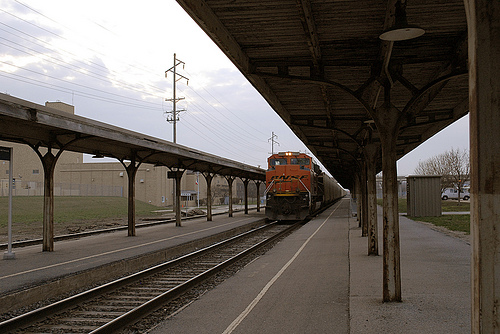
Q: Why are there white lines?
A: For boundaries.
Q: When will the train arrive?
A: Now.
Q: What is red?
A: The train.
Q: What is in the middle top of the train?
A: A headlight.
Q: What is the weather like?
A: Cloudy.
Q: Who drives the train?
A: The conductor.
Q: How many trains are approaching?
A: Just one.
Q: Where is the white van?
A: On the right side of the picture behind the fence.